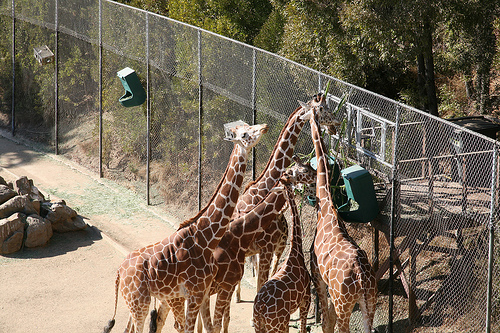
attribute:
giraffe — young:
[112, 110, 269, 331]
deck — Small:
[390, 124, 499, 231]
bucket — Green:
[107, 41, 178, 126]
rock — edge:
[8, 191, 38, 221]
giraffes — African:
[141, 108, 393, 331]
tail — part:
[101, 275, 128, 320]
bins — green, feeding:
[318, 153, 371, 214]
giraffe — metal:
[102, 118, 267, 331]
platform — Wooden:
[348, 75, 484, 329]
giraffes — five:
[91, 88, 399, 332]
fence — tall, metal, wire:
[0, 24, 482, 276]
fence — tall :
[1, 4, 499, 331]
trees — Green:
[297, 12, 454, 65]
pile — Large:
[0, 173, 90, 256]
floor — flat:
[0, 137, 310, 329]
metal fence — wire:
[2, 3, 204, 200]